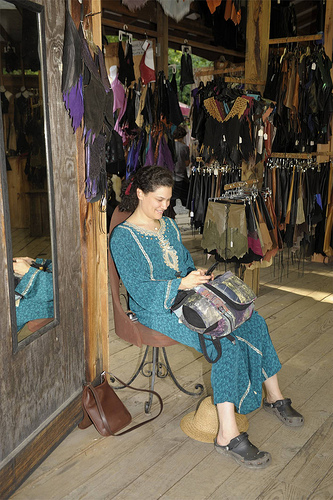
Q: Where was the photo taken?
A: In a store.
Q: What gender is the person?
A: Female.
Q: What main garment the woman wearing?
A: A dress.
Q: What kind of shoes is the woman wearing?
A: Crocs.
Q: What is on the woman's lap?
A: A bag.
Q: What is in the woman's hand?
A: A phone.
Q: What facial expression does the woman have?
A: A smile.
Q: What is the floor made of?
A: Wood.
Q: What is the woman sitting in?
A: A chair.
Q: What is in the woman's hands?
A: A phone.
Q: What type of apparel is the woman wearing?
A: A dress.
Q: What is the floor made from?
A: Wood.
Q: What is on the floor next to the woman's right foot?
A: Hat.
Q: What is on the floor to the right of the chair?
A: A handbag.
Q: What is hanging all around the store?
A: Clothing.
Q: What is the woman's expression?
A: Smiling.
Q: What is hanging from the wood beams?
A: Clothing.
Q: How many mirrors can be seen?
A: One.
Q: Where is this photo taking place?
A: A shop.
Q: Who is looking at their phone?
A: The woman.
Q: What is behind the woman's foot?
A: A hat.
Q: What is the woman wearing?
A: A dress.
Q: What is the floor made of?
A: Wood.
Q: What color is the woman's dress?
A: Blue.